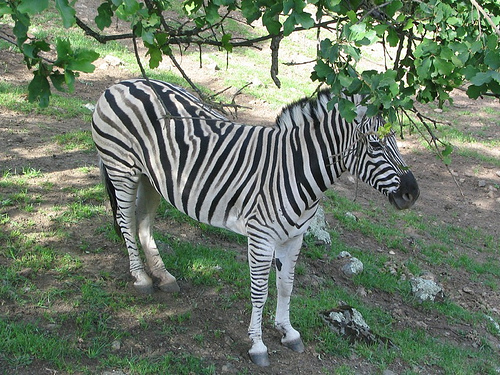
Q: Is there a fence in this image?
A: No, there are no fences.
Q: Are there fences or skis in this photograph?
A: No, there are no fences or skis.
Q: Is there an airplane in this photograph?
A: No, there are no airplanes.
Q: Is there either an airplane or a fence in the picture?
A: No, there are no airplanes or fences.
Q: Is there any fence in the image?
A: No, there are no fences.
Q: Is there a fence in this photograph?
A: No, there are no fences.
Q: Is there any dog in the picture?
A: No, there are no dogs.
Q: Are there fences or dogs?
A: No, there are no dogs or fences.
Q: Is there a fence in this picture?
A: No, there are no fences.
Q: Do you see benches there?
A: No, there are no benches.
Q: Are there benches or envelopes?
A: No, there are no benches or envelopes.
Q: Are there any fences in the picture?
A: No, there are no fences.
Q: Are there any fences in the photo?
A: No, there are no fences.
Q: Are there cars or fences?
A: No, there are no fences or cars.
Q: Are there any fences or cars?
A: No, there are no fences or cars.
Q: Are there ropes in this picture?
A: No, there are no ropes.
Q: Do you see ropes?
A: No, there are no ropes.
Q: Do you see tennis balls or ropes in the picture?
A: No, there are no ropes or tennis balls.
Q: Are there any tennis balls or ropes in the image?
A: No, there are no ropes or tennis balls.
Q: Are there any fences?
A: No, there are no fences.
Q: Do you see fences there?
A: No, there are no fences.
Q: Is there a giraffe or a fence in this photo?
A: No, there are no fences or giraffes.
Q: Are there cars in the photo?
A: No, there are no cars.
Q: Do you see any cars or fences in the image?
A: No, there are no cars or fences.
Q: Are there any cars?
A: No, there are no cars.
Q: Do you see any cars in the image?
A: No, there are no cars.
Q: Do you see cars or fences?
A: No, there are no cars or fences.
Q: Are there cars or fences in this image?
A: No, there are no cars or fences.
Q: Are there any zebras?
A: Yes, there is a zebra.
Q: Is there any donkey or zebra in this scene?
A: Yes, there is a zebra.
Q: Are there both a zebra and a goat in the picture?
A: No, there is a zebra but no goats.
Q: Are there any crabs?
A: No, there are no crabs.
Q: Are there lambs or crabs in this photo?
A: No, there are no crabs or lambs.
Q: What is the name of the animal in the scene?
A: The animal is a zebra.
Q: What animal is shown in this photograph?
A: The animal is a zebra.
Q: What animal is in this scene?
A: The animal is a zebra.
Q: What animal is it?
A: The animal is a zebra.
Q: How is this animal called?
A: This is a zebra.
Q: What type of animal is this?
A: This is a zebra.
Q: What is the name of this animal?
A: This is a zebra.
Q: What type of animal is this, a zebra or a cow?
A: This is a zebra.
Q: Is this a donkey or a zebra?
A: This is a zebra.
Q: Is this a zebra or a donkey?
A: This is a zebra.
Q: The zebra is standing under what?
A: The zebra is standing under the tree.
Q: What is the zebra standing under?
A: The zebra is standing under the tree.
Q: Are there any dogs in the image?
A: No, there are no dogs.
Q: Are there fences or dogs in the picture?
A: No, there are no dogs or fences.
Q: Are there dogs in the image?
A: No, there are no dogs.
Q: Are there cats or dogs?
A: No, there are no dogs or cats.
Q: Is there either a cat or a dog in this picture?
A: No, there are no dogs or cats.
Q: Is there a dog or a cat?
A: No, there are no dogs or cats.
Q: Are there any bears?
A: No, there are no bears.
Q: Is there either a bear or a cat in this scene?
A: No, there are no bears or cats.